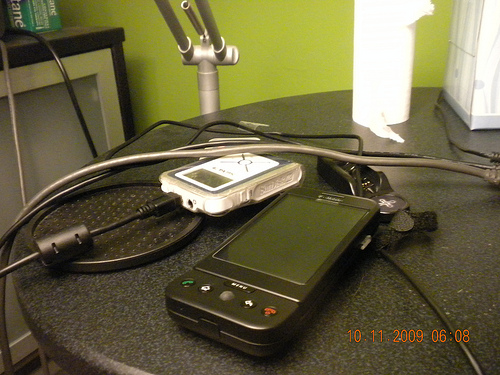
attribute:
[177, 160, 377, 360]
cellphone — black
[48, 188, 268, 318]
charger — connected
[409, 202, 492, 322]
table — black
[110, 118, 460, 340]
wall — green, painted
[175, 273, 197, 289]
button — green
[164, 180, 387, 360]
phone — black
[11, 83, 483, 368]
table — black, circular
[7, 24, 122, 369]
cabinet — black, white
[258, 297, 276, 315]
button — red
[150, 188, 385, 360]
phone — black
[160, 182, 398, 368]
phone — black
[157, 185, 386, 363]
cellphone — black, bulky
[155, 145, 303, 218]
device — white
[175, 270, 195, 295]
button — green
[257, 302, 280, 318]
button — red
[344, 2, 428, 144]
towels — paper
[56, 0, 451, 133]
wall — green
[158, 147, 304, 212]
object — white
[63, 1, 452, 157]
wall — green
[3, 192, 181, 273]
cord — black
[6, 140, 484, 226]
cord — gray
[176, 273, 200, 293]
button — green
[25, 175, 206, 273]
object — round, black